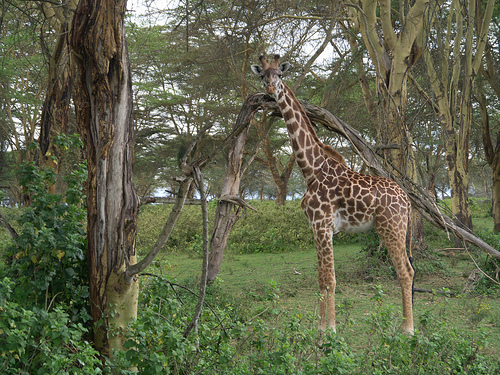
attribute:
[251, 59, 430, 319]
giraffe — standing, looking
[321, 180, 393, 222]
spots — white, brown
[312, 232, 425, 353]
legs — large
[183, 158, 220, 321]
branch — broken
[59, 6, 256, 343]
trees — together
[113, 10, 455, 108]
sky — blue, cloudy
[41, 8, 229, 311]
tree — different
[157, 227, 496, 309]
grass — green, soem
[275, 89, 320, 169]
neck — long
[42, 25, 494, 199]
forest — green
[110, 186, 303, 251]
bushes — green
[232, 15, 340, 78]
branches — hanging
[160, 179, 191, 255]
stem — brown, thick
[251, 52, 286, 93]
head — long, big